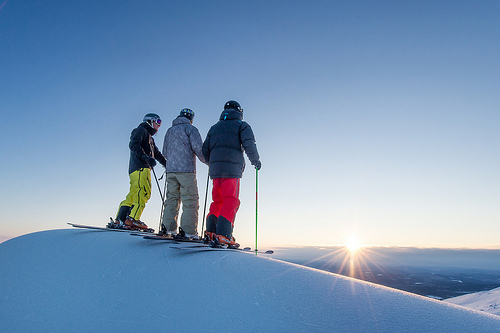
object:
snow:
[0, 228, 500, 332]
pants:
[205, 176, 240, 238]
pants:
[118, 167, 152, 220]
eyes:
[156, 120, 162, 125]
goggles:
[146, 117, 162, 126]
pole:
[254, 162, 259, 250]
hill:
[269, 244, 499, 292]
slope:
[236, 253, 500, 332]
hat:
[224, 100, 243, 112]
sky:
[0, 0, 500, 250]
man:
[107, 113, 166, 230]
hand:
[145, 156, 157, 168]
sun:
[340, 229, 376, 252]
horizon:
[238, 239, 500, 253]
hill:
[0, 224, 500, 332]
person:
[200, 100, 262, 250]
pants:
[160, 173, 199, 235]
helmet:
[142, 112, 162, 125]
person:
[159, 107, 209, 242]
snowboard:
[174, 242, 207, 245]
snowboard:
[129, 233, 164, 236]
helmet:
[223, 100, 244, 114]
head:
[219, 99, 245, 121]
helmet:
[179, 108, 196, 120]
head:
[178, 107, 195, 119]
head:
[141, 113, 162, 135]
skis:
[72, 224, 125, 229]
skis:
[182, 248, 246, 252]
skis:
[143, 236, 199, 242]